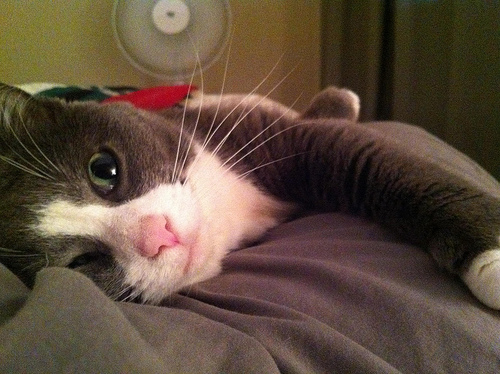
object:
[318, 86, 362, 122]
paw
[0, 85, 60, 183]
whiskers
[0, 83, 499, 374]
bed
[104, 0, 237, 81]
fan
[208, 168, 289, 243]
chest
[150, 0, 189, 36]
white circle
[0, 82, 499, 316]
cat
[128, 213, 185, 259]
nose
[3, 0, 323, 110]
wall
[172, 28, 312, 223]
hair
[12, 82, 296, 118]
pillow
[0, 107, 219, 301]
cat's face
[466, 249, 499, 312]
paw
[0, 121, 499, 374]
blanket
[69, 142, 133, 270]
cat's eye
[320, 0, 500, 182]
curtain